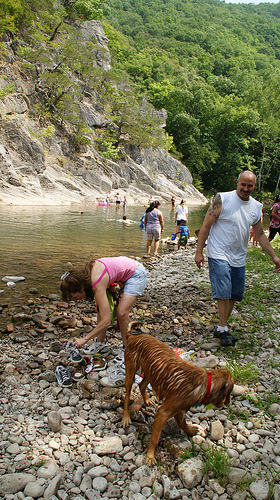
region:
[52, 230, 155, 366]
Woman wearing pink shirt.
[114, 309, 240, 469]
Brown colored dogs fur is wet.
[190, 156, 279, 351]
Man wearing white shirt and jean shorts.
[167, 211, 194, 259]
Young child wearing blue holding bucket.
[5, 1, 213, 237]
Water at bottom of a rock mountain.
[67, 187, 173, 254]
People swimming in water.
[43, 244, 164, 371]
lady bending over to pick up shoe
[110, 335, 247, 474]
brown wet dog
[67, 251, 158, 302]
lady wearing pink shirt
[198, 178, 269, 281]
man wearing white shirt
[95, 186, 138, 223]
people in water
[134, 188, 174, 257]
lady standing in water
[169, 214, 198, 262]
little girl in water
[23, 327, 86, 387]
pair of sneakers on ground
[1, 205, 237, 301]
lake of water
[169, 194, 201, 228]
lady standing in water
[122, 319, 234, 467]
a wet golden retriever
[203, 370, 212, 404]
a red collar on the dog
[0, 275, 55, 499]
a rocky river bank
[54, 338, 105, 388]
a pile of sneakers on the rocks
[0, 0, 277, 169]
the side of a mountain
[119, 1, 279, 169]
a thick forest next to the river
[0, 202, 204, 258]
a river in the mountains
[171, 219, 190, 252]
a child walking on the river bank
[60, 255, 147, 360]
a lady looking for her shoes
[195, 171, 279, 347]
a man wearing a cut off t-shirt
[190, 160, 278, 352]
man wearing gray shirt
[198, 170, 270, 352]
man wearnig blue jeans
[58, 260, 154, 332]
woman wearing pink shirt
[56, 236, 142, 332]
woman wearing blue jeans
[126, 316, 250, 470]
dog standing on rocks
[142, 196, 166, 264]
woman wearing a purble shirt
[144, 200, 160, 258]
woman wearing plaid shorts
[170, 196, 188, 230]
woman wearing white shirt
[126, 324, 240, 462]
dog wearing red collar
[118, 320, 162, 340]
tail on a dog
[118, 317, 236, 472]
brown wet dog standing on rocks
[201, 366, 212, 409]
red collar on dog's neck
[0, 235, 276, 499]
tan rocks on side of water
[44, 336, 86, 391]
black and white sneakers on tan rocks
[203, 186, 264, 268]
white sleeveless shirt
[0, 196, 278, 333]
body of water on side of rocks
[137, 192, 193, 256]
people standing at edge of water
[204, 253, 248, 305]
pair of denim shorts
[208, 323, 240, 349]
pair of black shoes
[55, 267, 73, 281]
hair clip in woman's hair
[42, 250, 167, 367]
lady bending over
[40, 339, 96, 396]
sneakers on the rocks